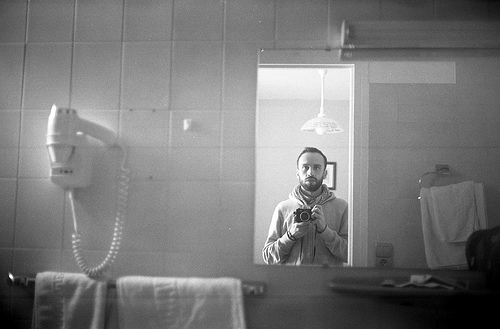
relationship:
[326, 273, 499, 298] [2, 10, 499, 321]
ring in a bathroom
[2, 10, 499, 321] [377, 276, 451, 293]
bathroom holding toothbrush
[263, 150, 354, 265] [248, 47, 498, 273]
reflection in mirror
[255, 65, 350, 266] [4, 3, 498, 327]
man mirror on wall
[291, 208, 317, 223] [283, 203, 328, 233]
camera in hands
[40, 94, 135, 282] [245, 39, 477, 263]
blow dryer by mirror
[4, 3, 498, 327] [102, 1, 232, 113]
wall has rectangular tiles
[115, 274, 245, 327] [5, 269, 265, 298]
towel on rack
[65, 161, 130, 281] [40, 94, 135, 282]
cord to blow dryer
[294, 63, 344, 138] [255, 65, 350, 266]
lamp in man mirror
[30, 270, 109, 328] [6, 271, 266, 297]
towel on rack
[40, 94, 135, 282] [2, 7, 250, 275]
blow dryer attached to wall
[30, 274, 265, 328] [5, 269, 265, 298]
towel hanging on rack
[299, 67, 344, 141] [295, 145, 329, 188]
ceiling above man's head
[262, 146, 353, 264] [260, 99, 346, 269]
picture frame on wall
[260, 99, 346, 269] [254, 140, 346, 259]
wall behind man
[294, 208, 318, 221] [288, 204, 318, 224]
camera in hands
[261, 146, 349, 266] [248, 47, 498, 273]
face person taking picture in mirror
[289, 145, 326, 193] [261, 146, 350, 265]
head of person